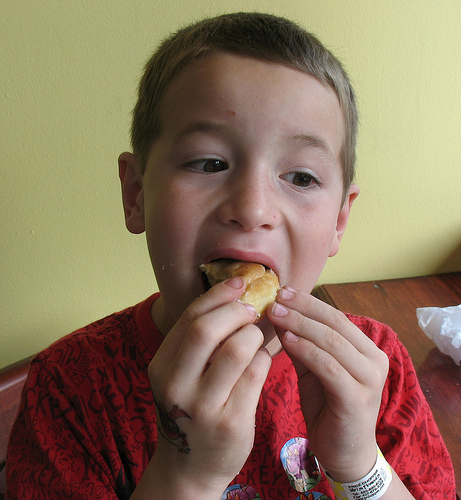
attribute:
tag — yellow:
[309, 443, 397, 499]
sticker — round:
[279, 438, 321, 493]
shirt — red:
[4, 290, 457, 498]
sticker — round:
[221, 483, 261, 499]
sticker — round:
[291, 491, 331, 499]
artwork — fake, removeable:
[148, 383, 193, 458]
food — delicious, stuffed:
[197, 258, 281, 320]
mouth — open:
[196, 246, 284, 308]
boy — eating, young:
[6, 11, 457, 499]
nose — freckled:
[215, 167, 286, 231]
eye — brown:
[183, 158, 229, 172]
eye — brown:
[278, 171, 319, 187]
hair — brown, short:
[127, 10, 359, 209]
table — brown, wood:
[310, 270, 460, 499]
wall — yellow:
[0, 0, 460, 371]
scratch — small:
[227, 108, 237, 116]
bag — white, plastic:
[414, 303, 461, 365]